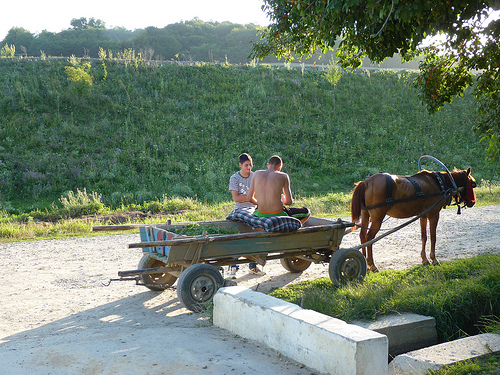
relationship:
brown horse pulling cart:
[351, 165, 474, 270] [87, 208, 367, 308]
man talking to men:
[245, 155, 310, 225] [229, 151, 257, 210]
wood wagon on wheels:
[80, 218, 385, 306] [122, 245, 372, 326]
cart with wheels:
[122, 207, 360, 295] [134, 249, 369, 315]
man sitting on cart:
[245, 151, 292, 222] [85, 211, 367, 295]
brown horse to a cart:
[351, 165, 474, 270] [85, 211, 367, 295]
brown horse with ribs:
[351, 165, 474, 270] [398, 175, 434, 199]